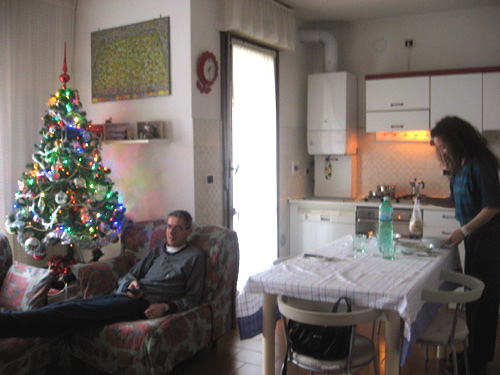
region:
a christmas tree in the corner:
[16, 42, 126, 269]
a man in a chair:
[4, 200, 246, 345]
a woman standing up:
[425, 107, 498, 272]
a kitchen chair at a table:
[271, 259, 403, 366]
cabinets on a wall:
[374, 71, 465, 141]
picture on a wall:
[85, 13, 178, 108]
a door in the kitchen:
[228, 21, 285, 211]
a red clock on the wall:
[192, 42, 227, 100]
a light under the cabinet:
[378, 115, 429, 150]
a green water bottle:
[370, 196, 414, 249]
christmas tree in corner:
[8, 36, 134, 251]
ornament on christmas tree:
[108, 220, 119, 240]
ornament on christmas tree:
[55, 191, 75, 205]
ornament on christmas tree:
[23, 236, 41, 258]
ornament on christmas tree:
[68, 174, 88, 191]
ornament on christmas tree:
[77, 130, 93, 144]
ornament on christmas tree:
[8, 222, 18, 236]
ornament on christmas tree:
[74, 119, 86, 135]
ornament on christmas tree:
[43, 153, 55, 165]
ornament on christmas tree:
[61, 108, 79, 127]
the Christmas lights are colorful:
[21, 75, 137, 285]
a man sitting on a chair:
[97, 210, 233, 332]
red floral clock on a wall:
[190, 48, 224, 95]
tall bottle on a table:
[377, 196, 395, 253]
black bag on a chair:
[282, 296, 353, 361]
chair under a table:
[417, 268, 481, 373]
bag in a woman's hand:
[407, 192, 426, 236]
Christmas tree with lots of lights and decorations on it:
[2, 88, 134, 263]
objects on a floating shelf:
[87, 116, 170, 146]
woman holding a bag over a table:
[406, 114, 498, 373]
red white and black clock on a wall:
[191, 46, 221, 100]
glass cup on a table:
[348, 232, 370, 252]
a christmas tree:
[4, 11, 158, 332]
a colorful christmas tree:
[12, 29, 161, 315]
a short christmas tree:
[26, 32, 178, 297]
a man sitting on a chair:
[20, 151, 270, 366]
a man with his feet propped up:
[10, 193, 247, 374]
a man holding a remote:
[94, 186, 267, 319]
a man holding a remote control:
[80, 184, 240, 333]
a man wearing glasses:
[137, 193, 225, 261]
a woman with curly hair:
[414, 108, 492, 185]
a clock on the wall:
[171, 4, 276, 149]